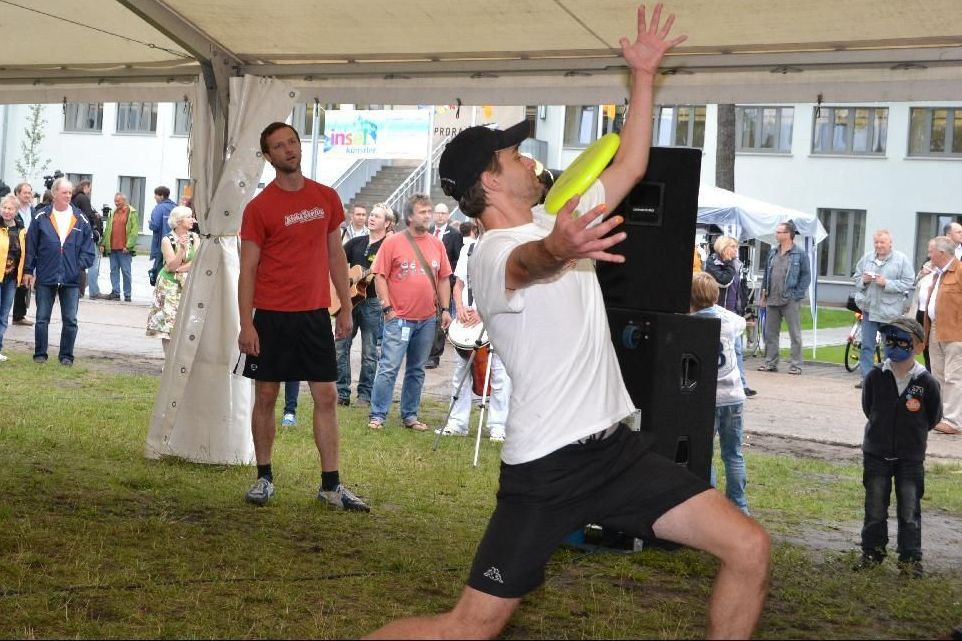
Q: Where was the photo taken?
A: Under a tent.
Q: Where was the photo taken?
A: At gathering.